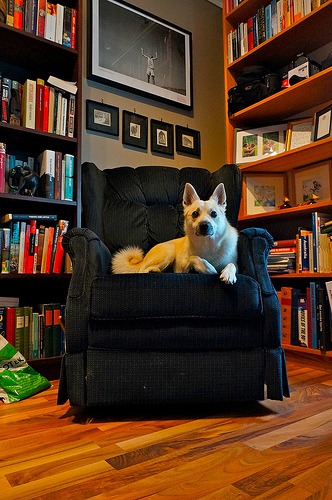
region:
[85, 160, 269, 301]
a dog in a chair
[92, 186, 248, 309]
a medium white dog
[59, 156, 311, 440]
a black chair with dog in it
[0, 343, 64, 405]
a green and white bag on floor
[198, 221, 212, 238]
a black nose on the dog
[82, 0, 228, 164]
pictures hanging on the wall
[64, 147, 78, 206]
a blue and white book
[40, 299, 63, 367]
two black books with red on them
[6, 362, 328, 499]
a hard wood floor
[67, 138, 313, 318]
a dog laying on a chair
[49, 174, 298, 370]
a dog on a chair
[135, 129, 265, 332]
a large dog on a chair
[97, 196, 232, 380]
a large dog on a chiar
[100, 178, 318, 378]
a large dog laying inside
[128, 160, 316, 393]
a dog laying inside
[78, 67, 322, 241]
a wall with picture frames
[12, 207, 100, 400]
a shelf with books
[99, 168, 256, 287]
a dog laying in a chair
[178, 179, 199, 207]
the ear of a dog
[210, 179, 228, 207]
the ear of a dog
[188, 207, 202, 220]
the eye of a dog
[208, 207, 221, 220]
the eye of a dog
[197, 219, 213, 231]
the nose of a dog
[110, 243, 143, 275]
the tail of a dog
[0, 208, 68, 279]
books on a book shelf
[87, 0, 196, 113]
a picture in a frame on a wall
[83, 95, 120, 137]
a picture in a frame on a wall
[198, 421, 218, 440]
par tof a flor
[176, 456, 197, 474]
part of a floor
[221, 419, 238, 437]
part of a floor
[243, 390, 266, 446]
apr tfo a shade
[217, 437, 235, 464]
part of a floor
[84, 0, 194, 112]
a black framed picture on the wall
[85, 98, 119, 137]
a black framed picture on the wall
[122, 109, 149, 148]
a black framed picture on the wall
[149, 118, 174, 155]
a black framed picture on the wall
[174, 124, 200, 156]
a black framed picture on the wall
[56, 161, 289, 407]
a black recliner rocking chair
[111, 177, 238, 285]
a white dog in a chair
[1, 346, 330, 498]
light brown hard wood flooring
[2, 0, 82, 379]
a book shelf full of books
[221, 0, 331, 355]
a book shelf full of books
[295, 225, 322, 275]
a book on the shelf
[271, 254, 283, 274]
a book on the shelf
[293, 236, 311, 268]
a book on the shelfa book on the shelf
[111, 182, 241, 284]
the dog is white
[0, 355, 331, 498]
the floor is wood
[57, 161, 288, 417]
the chair is dark blue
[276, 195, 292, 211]
knicknack is on the shelf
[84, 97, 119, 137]
picture has a gray frame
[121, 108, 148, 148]
picture is on the wall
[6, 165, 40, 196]
black statue is on the bookshelf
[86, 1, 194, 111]
picture border is white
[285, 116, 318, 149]
picture frame is gold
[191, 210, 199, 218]
dog's eye is black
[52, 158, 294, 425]
black rocking recliner chair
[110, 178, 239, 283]
white alert dog sitting in black chair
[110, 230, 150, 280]
curled white fluffy tail of dog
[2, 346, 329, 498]
golden wooden inlaid flooring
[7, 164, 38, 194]
black people statues on shelf